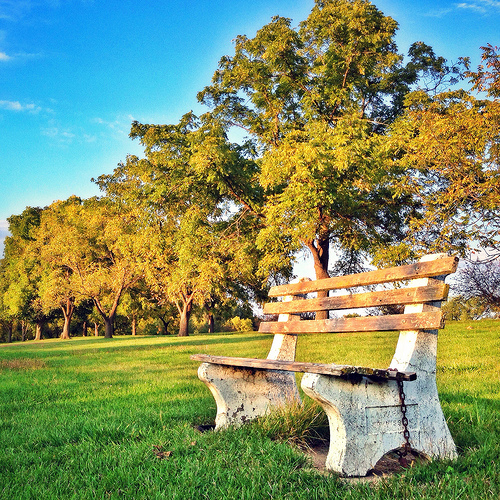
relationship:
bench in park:
[192, 253, 464, 472] [2, 3, 496, 498]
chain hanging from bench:
[396, 372, 420, 448] [192, 253, 464, 472]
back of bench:
[257, 257, 459, 333] [192, 253, 464, 472]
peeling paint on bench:
[229, 403, 257, 427] [192, 253, 464, 472]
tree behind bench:
[217, 5, 397, 327] [192, 253, 464, 472]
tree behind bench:
[111, 115, 260, 332] [192, 253, 464, 472]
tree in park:
[111, 115, 260, 332] [2, 3, 496, 498]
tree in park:
[217, 5, 397, 327] [2, 3, 496, 498]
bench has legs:
[192, 253, 464, 472] [303, 374, 459, 474]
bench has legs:
[192, 253, 464, 472] [194, 364, 299, 429]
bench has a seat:
[192, 253, 464, 472] [191, 351, 416, 383]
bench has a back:
[192, 253, 464, 472] [257, 257, 459, 333]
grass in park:
[2, 328, 496, 499] [2, 3, 496, 498]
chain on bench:
[396, 372, 420, 448] [192, 253, 464, 472]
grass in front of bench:
[2, 328, 496, 499] [192, 253, 464, 472]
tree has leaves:
[217, 5, 397, 327] [299, 140, 369, 207]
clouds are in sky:
[2, 98, 52, 123] [0, 0, 499, 206]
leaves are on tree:
[299, 140, 369, 207] [217, 5, 397, 327]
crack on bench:
[396, 357, 437, 376] [192, 253, 464, 472]